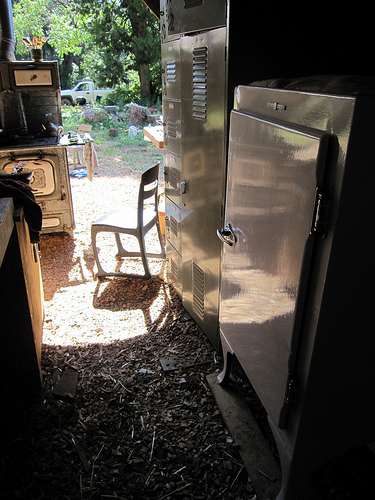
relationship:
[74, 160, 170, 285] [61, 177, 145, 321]
chair in the sun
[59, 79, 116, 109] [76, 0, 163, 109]
truck behind tree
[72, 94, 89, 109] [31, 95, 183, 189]
grill in yard